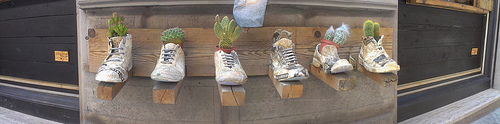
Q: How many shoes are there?
A: 6.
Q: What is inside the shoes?
A: Plants.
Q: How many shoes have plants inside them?
A: 5.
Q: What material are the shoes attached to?
A: Wood.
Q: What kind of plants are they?
A: Cacti.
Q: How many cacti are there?
A: 5.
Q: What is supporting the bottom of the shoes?
A: Wood.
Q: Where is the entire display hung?
A: Against a concrete wall.